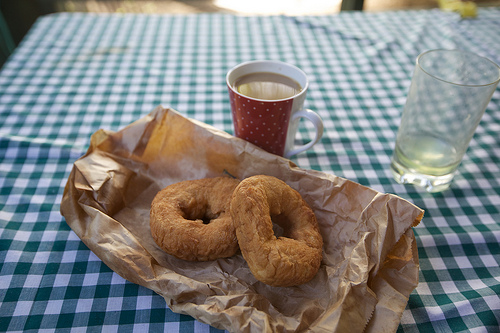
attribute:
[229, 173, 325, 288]
donut — brown, round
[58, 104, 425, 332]
paper bag — brown, wrinkled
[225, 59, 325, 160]
cup — full, white, red, breakable, coffee mug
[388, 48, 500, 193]
drinking glass — breakable, clear, tall, nearly empty, almost empty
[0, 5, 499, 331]
table cloth — green, white, color green, checkered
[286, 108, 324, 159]
handle — white